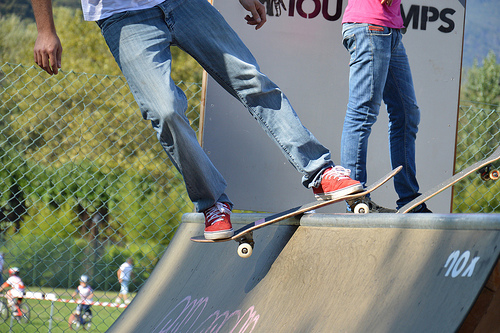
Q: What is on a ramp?
A: Skateboards.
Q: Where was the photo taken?
A: Skatepark.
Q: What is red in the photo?
A: Sneakers.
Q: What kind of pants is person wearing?
A: Blue jeans.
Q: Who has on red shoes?
A: The boy.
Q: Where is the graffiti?
A: On ramp.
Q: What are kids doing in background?
A: Riding bikes.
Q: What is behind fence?
A: Trees.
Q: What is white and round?
A: Wheels.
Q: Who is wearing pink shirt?
A: The girl.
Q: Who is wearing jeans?
A: Both people.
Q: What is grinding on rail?
A: Skateboard.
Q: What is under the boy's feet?
A: Skateboard.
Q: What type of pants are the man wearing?
A: Blue jeans.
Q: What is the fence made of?
A: Metal.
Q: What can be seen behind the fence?
A: Children.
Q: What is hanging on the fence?
A: A billboard.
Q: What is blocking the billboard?
A: A woman.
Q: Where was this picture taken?
A: Park.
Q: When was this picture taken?
A: Summer day.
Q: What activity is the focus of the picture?
A: Skateboarding.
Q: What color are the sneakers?
A: Red.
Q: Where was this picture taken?
A: A skate park.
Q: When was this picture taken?
A: Daytime.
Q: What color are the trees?
A: Green.